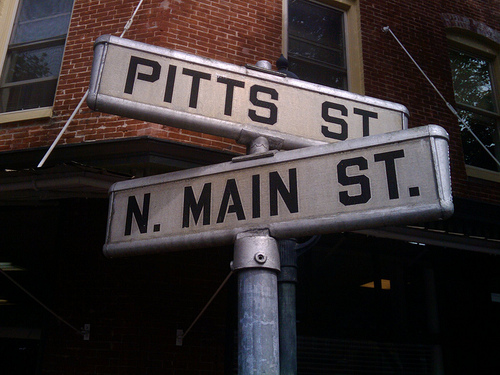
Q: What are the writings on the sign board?
A: N.main street.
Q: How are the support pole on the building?
A: They are white.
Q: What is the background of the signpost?
A: A brick building.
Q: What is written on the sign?
A: PITTS ST.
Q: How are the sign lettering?
A: They are black.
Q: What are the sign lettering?
A: Street sign.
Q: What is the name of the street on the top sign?
A: Pitts Street.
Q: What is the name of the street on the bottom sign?
A: North Main Street.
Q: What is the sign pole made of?
A: Metal.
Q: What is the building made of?
A: Brick.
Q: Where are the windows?
A: On the building.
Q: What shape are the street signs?
A: Rectangular.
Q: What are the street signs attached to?
A: The sign pole.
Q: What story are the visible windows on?
A: The second floor.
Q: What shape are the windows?
A: Rectangular.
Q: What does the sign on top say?
A: Pitts st.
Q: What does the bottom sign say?
A: N. Main St.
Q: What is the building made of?
A: Brick.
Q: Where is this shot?
A: Interseciton.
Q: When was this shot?
A: Daytime.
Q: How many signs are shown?
A: 2.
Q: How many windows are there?
A: 3.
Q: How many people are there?
A: 0.